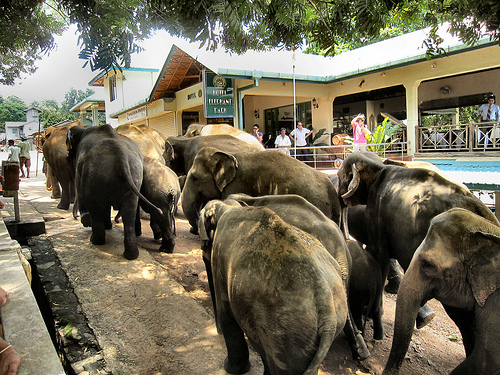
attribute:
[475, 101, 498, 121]
shirt — blue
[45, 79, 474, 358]
elephants — parading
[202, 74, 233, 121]
sign — green and gold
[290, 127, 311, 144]
shirt — white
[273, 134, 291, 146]
shirt — white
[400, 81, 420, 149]
column — white